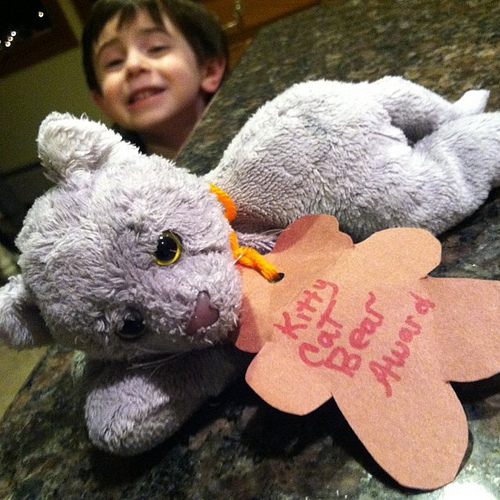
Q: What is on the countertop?
A: A cat.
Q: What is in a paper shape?
A: A bear.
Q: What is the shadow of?
A: A cat.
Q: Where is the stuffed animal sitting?
A: Countertop.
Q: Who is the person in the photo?
A: A young boy.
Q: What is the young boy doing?
A: Looking at the teddy bear on the countertop.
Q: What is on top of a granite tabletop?
A: A white stuffed animal.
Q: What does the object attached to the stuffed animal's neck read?
A: Kitty Cat Bear Award.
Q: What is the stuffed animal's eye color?
A: Green.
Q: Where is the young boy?
A: In the kitchen by the counter top.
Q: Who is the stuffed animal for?
A: The little boy.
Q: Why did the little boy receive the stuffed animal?
A: As an award.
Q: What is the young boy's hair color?
A: Dark brown.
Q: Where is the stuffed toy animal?
A: On the counter.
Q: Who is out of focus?
A: The little boy.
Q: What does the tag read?
A: Kitty Cat Bear Award.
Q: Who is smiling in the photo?
A: The little boy.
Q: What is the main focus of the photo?
A: The cat.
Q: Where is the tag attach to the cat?
A: Around the neck.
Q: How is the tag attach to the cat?
A: With string.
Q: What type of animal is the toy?
A: A cat.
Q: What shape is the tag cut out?
A: A teddy bear.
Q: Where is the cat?
A: On the counter.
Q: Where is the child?
A: Behind the cat.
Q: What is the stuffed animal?
A: A kitty cat bear.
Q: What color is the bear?
A: Gray.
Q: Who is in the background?
A: A child.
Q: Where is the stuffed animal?
A: On the counter.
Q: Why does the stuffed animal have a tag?
A: It is an award.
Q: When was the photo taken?
A: Nighttime.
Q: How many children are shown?
A: One.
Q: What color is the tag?
A: Brown.